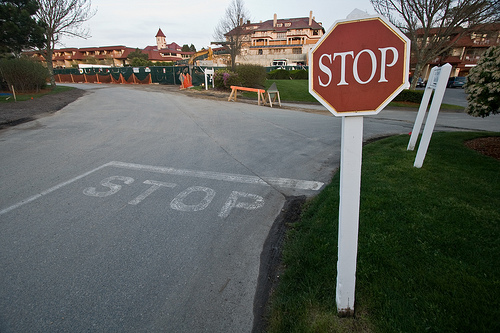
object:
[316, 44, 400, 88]
stop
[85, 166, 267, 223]
stop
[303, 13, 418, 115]
sign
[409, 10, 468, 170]
sign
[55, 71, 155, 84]
netting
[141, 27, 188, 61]
building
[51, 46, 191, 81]
apartments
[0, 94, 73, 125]
area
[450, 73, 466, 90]
car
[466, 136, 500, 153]
mulch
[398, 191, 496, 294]
lawn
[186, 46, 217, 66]
vehicle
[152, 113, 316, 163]
street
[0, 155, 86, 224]
line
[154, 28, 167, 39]
tower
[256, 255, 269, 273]
water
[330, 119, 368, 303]
wood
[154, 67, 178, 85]
gate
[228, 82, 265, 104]
sawhorse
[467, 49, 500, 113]
tree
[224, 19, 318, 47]
building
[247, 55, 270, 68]
stone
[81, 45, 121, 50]
roof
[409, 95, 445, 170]
posts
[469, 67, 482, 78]
flowers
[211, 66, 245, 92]
shrub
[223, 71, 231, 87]
flowers